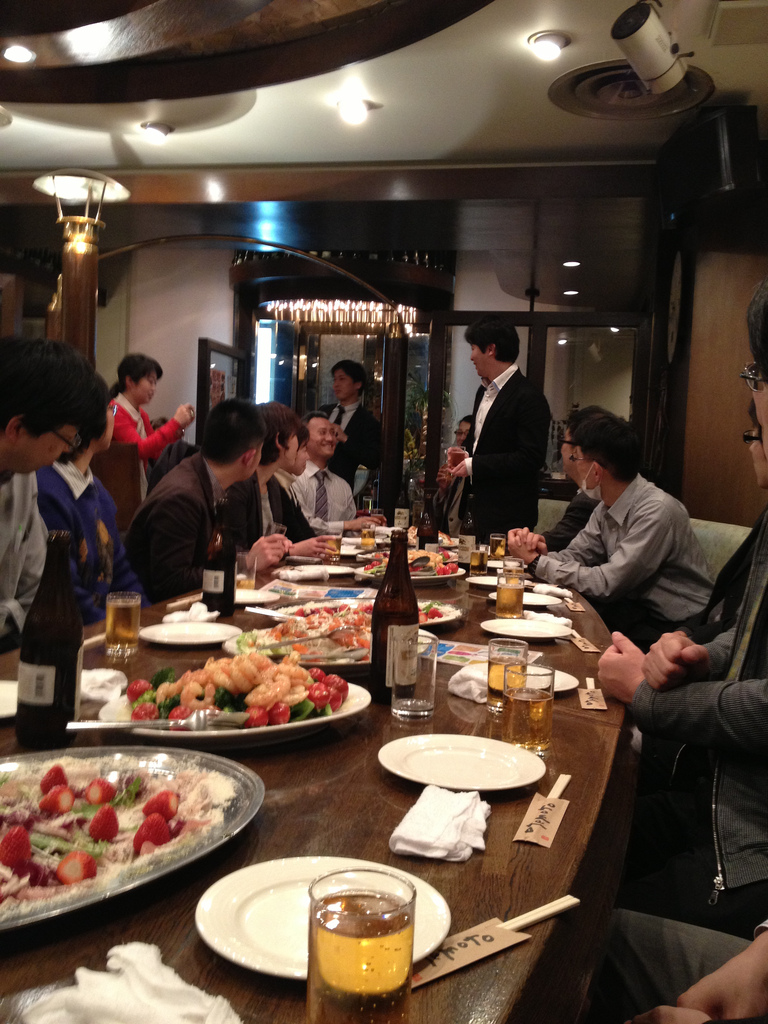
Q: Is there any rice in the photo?
A: No, there is no rice.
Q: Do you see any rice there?
A: No, there is no rice.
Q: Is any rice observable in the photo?
A: No, there is no rice.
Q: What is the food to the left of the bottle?
A: The food is shrimp.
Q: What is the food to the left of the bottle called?
A: The food is shrimp.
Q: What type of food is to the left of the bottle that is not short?
A: The food is shrimp.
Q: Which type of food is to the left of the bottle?
A: The food is shrimp.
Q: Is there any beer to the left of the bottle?
A: No, there is shrimp to the left of the bottle.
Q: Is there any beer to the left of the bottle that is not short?
A: No, there is shrimp to the left of the bottle.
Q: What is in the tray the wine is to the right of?
A: The shrimp is in the tray.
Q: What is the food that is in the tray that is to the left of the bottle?
A: The food is shrimp.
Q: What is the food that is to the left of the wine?
A: The food is shrimp.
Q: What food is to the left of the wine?
A: The food is shrimp.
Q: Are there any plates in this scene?
A: Yes, there is a plate.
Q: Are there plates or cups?
A: Yes, there is a plate.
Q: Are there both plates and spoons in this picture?
A: No, there is a plate but no spoons.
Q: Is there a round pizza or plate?
A: Yes, there is a round plate.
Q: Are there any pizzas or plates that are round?
A: Yes, the plate is round.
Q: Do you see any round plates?
A: Yes, there is a round plate.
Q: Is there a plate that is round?
A: Yes, there is a plate that is round.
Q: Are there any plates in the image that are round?
A: Yes, there is a plate that is round.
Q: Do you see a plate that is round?
A: Yes, there is a plate that is round.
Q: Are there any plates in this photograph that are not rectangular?
A: Yes, there is a round plate.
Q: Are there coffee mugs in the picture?
A: No, there are no coffee mugs.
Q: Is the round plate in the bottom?
A: Yes, the plate is in the bottom of the image.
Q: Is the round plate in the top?
A: No, the plate is in the bottom of the image.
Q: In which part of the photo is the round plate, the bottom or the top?
A: The plate is in the bottom of the image.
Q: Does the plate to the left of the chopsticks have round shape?
A: Yes, the plate is round.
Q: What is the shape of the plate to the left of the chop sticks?
A: The plate is round.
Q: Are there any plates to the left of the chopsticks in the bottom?
A: Yes, there is a plate to the left of the chopsticks.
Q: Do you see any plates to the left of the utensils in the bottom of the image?
A: Yes, there is a plate to the left of the chopsticks.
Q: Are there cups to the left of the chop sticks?
A: No, there is a plate to the left of the chop sticks.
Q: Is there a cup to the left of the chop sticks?
A: No, there is a plate to the left of the chop sticks.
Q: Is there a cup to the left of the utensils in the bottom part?
A: No, there is a plate to the left of the chop sticks.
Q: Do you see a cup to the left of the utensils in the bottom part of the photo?
A: No, there is a plate to the left of the chop sticks.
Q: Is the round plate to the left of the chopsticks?
A: Yes, the plate is to the left of the chopsticks.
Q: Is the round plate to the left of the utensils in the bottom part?
A: Yes, the plate is to the left of the chopsticks.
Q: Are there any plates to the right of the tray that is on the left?
A: Yes, there is a plate to the right of the tray.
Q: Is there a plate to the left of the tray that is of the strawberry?
A: No, the plate is to the right of the tray.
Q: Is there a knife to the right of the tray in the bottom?
A: No, there is a plate to the right of the tray.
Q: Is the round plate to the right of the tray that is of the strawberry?
A: Yes, the plate is to the right of the tray.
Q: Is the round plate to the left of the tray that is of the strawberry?
A: No, the plate is to the right of the tray.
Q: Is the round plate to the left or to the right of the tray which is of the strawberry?
A: The plate is to the right of the tray.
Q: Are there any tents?
A: No, there are no tents.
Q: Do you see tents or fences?
A: No, there are no tents or fences.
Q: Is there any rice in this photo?
A: No, there is no rice.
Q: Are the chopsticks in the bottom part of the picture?
A: Yes, the chopsticks are in the bottom of the image.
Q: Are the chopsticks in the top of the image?
A: No, the chopsticks are in the bottom of the image.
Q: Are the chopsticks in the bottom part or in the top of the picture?
A: The chopsticks are in the bottom of the image.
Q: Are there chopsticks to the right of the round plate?
A: Yes, there are chopsticks to the right of the plate.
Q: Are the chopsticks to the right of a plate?
A: Yes, the chopsticks are to the right of a plate.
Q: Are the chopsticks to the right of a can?
A: No, the chopsticks are to the right of a plate.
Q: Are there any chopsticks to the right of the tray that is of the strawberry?
A: Yes, there are chopsticks to the right of the tray.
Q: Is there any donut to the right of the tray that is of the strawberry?
A: No, there are chopsticks to the right of the tray.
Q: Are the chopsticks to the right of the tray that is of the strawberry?
A: Yes, the chopsticks are to the right of the tray.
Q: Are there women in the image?
A: Yes, there is a woman.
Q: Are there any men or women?
A: Yes, there is a woman.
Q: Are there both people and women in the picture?
A: Yes, there are both a woman and people.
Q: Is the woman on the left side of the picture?
A: Yes, the woman is on the left of the image.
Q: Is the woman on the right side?
A: No, the woman is on the left of the image.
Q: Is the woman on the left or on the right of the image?
A: The woman is on the left of the image.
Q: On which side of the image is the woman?
A: The woman is on the left of the image.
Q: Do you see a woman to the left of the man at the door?
A: Yes, there is a woman to the left of the man.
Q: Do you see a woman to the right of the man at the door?
A: No, the woman is to the left of the man.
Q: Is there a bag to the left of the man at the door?
A: No, there is a woman to the left of the man.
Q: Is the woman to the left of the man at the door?
A: Yes, the woman is to the left of the man.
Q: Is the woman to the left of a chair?
A: No, the woman is to the left of the man.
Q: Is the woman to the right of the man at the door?
A: No, the woman is to the left of the man.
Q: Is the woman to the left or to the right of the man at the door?
A: The woman is to the left of the man.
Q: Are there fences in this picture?
A: No, there are no fences.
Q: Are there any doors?
A: Yes, there is a door.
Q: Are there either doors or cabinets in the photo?
A: Yes, there is a door.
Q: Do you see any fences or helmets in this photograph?
A: No, there are no helmets or fences.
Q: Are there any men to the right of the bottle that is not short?
A: Yes, there is a man to the right of the bottle.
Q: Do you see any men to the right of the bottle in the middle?
A: Yes, there is a man to the right of the bottle.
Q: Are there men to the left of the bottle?
A: No, the man is to the right of the bottle.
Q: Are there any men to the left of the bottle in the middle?
A: No, the man is to the right of the bottle.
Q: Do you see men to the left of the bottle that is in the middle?
A: No, the man is to the right of the bottle.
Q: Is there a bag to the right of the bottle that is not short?
A: No, there is a man to the right of the bottle.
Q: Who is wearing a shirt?
A: The man is wearing a shirt.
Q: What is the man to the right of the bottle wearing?
A: The man is wearing a shirt.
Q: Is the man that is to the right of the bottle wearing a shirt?
A: Yes, the man is wearing a shirt.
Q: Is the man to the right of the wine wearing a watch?
A: No, the man is wearing a shirt.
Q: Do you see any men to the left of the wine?
A: No, the man is to the right of the wine.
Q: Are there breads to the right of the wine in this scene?
A: No, there is a man to the right of the wine.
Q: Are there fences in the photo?
A: No, there are no fences.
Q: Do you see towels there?
A: Yes, there is a towel.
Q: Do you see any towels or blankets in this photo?
A: Yes, there is a towel.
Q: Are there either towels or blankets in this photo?
A: Yes, there is a towel.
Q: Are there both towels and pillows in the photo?
A: No, there is a towel but no pillows.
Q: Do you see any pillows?
A: No, there are no pillows.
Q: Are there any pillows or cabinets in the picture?
A: No, there are no pillows or cabinets.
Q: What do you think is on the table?
A: The towel is on the table.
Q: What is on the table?
A: The towel is on the table.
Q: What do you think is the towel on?
A: The towel is on the table.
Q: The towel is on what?
A: The towel is on the table.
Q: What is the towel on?
A: The towel is on the table.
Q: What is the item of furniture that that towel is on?
A: The piece of furniture is a table.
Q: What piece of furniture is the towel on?
A: The towel is on the table.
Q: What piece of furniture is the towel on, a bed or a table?
A: The towel is on a table.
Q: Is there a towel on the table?
A: Yes, there is a towel on the table.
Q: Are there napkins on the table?
A: No, there is a towel on the table.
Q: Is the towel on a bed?
A: No, the towel is on the table.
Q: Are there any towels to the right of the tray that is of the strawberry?
A: Yes, there is a towel to the right of the tray.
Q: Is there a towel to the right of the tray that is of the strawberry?
A: Yes, there is a towel to the right of the tray.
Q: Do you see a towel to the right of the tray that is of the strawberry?
A: Yes, there is a towel to the right of the tray.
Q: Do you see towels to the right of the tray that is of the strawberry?
A: Yes, there is a towel to the right of the tray.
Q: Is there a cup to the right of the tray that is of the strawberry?
A: No, there is a towel to the right of the tray.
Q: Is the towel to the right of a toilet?
A: No, the towel is to the right of a tray.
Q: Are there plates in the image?
A: Yes, there is a plate.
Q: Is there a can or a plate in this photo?
A: Yes, there is a plate.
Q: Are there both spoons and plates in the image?
A: No, there is a plate but no spoons.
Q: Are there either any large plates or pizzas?
A: Yes, there is a large plate.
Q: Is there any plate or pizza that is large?
A: Yes, the plate is large.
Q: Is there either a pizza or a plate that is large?
A: Yes, the plate is large.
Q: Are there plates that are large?
A: Yes, there is a large plate.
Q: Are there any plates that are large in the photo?
A: Yes, there is a large plate.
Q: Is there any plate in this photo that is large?
A: Yes, there is a plate that is large.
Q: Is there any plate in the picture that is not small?
A: Yes, there is a large plate.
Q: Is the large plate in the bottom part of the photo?
A: Yes, the plate is in the bottom of the image.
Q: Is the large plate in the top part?
A: No, the plate is in the bottom of the image.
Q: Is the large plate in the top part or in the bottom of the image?
A: The plate is in the bottom of the image.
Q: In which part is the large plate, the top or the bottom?
A: The plate is in the bottom of the image.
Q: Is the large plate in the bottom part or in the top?
A: The plate is in the bottom of the image.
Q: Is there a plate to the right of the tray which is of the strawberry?
A: Yes, there is a plate to the right of the tray.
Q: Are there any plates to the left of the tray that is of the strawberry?
A: No, the plate is to the right of the tray.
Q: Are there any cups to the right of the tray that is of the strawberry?
A: No, there is a plate to the right of the tray.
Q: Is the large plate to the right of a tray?
A: Yes, the plate is to the right of a tray.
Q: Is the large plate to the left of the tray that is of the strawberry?
A: No, the plate is to the right of the tray.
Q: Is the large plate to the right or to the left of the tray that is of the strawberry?
A: The plate is to the right of the tray.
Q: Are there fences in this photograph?
A: No, there are no fences.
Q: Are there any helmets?
A: No, there are no helmets.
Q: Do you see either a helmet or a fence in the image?
A: No, there are no helmets or fences.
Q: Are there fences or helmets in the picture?
A: No, there are no helmets or fences.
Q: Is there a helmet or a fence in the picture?
A: No, there are no helmets or fences.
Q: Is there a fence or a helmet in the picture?
A: No, there are no helmets or fences.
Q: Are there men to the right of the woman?
A: Yes, there is a man to the right of the woman.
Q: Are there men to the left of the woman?
A: No, the man is to the right of the woman.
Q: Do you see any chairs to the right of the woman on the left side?
A: No, there is a man to the right of the woman.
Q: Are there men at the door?
A: Yes, there is a man at the door.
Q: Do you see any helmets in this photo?
A: No, there are no helmets.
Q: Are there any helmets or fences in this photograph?
A: No, there are no helmets or fences.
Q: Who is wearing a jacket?
A: The man is wearing a jacket.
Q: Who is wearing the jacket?
A: The man is wearing a jacket.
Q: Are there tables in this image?
A: Yes, there is a table.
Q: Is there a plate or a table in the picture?
A: Yes, there is a table.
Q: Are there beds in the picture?
A: No, there are no beds.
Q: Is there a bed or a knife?
A: No, there are no beds or knives.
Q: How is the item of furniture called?
A: The piece of furniture is a table.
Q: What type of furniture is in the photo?
A: The furniture is a table.